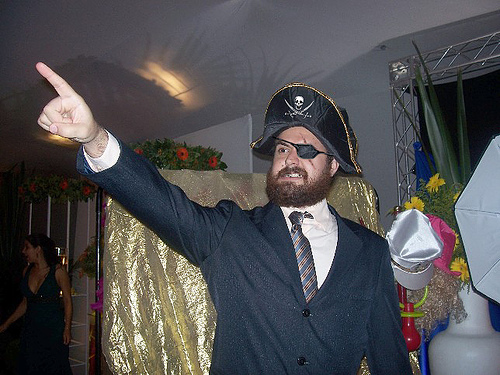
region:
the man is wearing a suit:
[211, 182, 433, 371]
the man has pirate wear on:
[223, 80, 338, 136]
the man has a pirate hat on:
[251, 70, 375, 157]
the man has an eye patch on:
[268, 135, 330, 165]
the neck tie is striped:
[275, 215, 332, 336]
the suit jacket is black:
[209, 215, 370, 374]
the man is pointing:
[2, 56, 114, 153]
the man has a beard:
[259, 154, 309, 194]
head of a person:
[243, 90, 350, 207]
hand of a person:
[13, 46, 105, 148]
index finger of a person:
[38, 65, 75, 99]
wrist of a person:
[88, 128, 128, 156]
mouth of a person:
[277, 165, 314, 185]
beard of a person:
[245, 168, 337, 209]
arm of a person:
[357, 245, 433, 372]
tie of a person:
[278, 200, 326, 327]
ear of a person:
[325, 146, 343, 173]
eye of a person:
[269, 131, 291, 153]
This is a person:
[28, 49, 411, 370]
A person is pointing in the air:
[20, 25, 455, 225]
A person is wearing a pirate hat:
[122, 6, 422, 371]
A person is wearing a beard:
[120, 31, 445, 356]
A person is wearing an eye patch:
[162, 40, 452, 356]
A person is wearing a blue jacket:
[136, 51, 441, 366]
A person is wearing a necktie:
[110, 45, 440, 345]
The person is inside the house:
[160, 25, 440, 355]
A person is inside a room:
[145, 45, 465, 355]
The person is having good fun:
[145, 42, 480, 360]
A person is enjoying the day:
[160, 31, 435, 355]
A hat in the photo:
[240, 84, 365, 176]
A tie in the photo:
[290, 212, 317, 298]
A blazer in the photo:
[234, 269, 296, 338]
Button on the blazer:
[296, 298, 312, 322]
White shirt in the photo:
[320, 222, 330, 267]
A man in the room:
[234, 130, 386, 352]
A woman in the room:
[12, 216, 99, 368]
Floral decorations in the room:
[114, 131, 234, 176]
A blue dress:
[25, 288, 65, 370]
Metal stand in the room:
[387, 76, 431, 165]